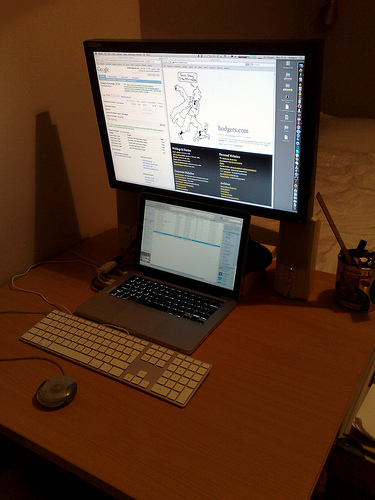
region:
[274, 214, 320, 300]
speaker with green light on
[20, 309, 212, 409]
falt keyboard on desk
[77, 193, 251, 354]
lap top is setting on desk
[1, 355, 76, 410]
appears to be a mouse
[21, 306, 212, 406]
input device for computer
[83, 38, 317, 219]
large computer screen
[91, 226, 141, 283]
cords connecting all devices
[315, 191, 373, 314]
cup with small utencils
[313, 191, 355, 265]
long object sticking out of cup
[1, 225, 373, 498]
brown wood desk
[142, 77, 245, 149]
the computer is on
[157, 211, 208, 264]
the laptop is on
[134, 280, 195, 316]
the keyboard is black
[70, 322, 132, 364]
the keyboard is white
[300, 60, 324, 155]
the monitor is black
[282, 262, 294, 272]
the light is on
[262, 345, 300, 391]
the table is brown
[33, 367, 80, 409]
the mouse is clear and gray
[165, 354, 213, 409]
the keyboard is sitting on the table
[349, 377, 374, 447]
the paper is white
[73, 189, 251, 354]
A silver laptop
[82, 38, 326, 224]
A large computer screen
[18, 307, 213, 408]
A flat computer keyboard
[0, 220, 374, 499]
A wooden computer table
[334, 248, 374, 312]
A conatiner holding items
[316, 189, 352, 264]
A long wooden ruler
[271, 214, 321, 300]
A white computer speaker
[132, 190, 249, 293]
A small laptop screen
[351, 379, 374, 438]
A white peice of paper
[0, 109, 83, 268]
A shadow on a wall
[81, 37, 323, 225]
a computer monitor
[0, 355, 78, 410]
a rounded computer mouse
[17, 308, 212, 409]
a white and tan keyboard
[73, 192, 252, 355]
an open laptop computer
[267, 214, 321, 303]
a computer speaker with green indicator light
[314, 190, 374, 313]
a cup with office supplies inside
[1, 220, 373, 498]
a square wooden desktop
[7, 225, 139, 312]
a bundle of electrical wires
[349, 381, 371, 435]
a corner of a pile of paper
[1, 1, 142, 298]
a smooth wall painted tan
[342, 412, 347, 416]
part of a table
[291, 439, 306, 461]
edge of a table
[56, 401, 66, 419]
part of a mouse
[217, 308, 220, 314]
part of a screen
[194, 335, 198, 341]
edge of a laptop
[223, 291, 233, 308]
part of a laptop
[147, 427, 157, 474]
part of a table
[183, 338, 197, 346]
part of a laptop